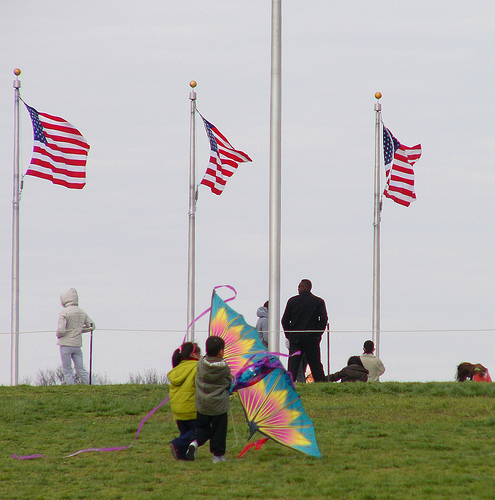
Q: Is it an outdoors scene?
A: Yes, it is outdoors.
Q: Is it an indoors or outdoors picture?
A: It is outdoors.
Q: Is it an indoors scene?
A: No, it is outdoors.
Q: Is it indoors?
A: No, it is outdoors.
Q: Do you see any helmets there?
A: No, there are no helmets.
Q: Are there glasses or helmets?
A: No, there are no helmets or glasses.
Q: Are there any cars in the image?
A: No, there are no cars.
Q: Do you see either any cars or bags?
A: No, there are no cars or bags.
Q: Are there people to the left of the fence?
A: Yes, there is a person to the left of the fence.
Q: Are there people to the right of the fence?
A: No, the person is to the left of the fence.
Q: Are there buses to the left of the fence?
A: No, there is a person to the left of the fence.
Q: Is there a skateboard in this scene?
A: No, there are no skateboards.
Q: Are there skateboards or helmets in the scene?
A: No, there are no skateboards or helmets.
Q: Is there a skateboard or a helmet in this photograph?
A: No, there are no skateboards or helmets.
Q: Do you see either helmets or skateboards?
A: No, there are no skateboards or helmets.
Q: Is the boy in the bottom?
A: Yes, the boy is in the bottom of the image.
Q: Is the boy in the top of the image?
A: No, the boy is in the bottom of the image.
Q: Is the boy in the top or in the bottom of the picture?
A: The boy is in the bottom of the image.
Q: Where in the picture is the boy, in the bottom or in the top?
A: The boy is in the bottom of the image.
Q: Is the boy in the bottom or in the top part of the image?
A: The boy is in the bottom of the image.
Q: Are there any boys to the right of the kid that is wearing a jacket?
A: Yes, there is a boy to the right of the kid.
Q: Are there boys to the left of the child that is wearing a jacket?
A: No, the boy is to the right of the kid.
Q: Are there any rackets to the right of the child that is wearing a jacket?
A: No, there is a boy to the right of the child.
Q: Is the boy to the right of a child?
A: Yes, the boy is to the right of a child.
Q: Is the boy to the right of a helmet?
A: No, the boy is to the right of a child.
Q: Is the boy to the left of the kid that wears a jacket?
A: No, the boy is to the right of the child.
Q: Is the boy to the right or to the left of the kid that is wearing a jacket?
A: The boy is to the right of the kid.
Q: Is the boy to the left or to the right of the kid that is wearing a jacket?
A: The boy is to the right of the kid.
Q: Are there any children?
A: Yes, there is a child.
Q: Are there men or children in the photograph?
A: Yes, there is a child.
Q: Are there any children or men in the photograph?
A: Yes, there is a child.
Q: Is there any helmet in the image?
A: No, there are no helmets.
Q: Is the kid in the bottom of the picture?
A: Yes, the kid is in the bottom of the image.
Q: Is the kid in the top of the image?
A: No, the kid is in the bottom of the image.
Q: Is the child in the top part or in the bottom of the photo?
A: The child is in the bottom of the image.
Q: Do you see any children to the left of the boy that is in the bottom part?
A: Yes, there is a child to the left of the boy.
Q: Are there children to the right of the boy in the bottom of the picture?
A: No, the child is to the left of the boy.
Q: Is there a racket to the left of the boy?
A: No, there is a child to the left of the boy.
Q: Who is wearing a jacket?
A: The kid is wearing a jacket.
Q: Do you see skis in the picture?
A: No, there are no skis.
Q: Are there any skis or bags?
A: No, there are no skis or bags.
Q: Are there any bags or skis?
A: No, there are no skis or bags.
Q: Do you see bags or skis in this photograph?
A: No, there are no skis or bags.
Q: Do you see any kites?
A: Yes, there is a kite.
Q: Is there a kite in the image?
A: Yes, there is a kite.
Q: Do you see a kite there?
A: Yes, there is a kite.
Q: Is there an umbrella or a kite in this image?
A: Yes, there is a kite.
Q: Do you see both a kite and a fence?
A: Yes, there are both a kite and a fence.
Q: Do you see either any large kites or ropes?
A: Yes, there is a large kite.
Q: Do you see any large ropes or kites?
A: Yes, there is a large kite.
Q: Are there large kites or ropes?
A: Yes, there is a large kite.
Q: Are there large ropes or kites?
A: Yes, there is a large kite.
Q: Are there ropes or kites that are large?
A: Yes, the kite is large.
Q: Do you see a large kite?
A: Yes, there is a large kite.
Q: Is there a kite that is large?
A: Yes, there is a kite that is large.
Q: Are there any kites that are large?
A: Yes, there is a kite that is large.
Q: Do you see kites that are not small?
A: Yes, there is a large kite.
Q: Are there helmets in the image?
A: No, there are no helmets.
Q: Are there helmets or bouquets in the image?
A: No, there are no helmets or bouquets.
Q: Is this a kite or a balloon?
A: This is a kite.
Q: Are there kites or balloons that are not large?
A: No, there is a kite but it is large.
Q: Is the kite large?
A: Yes, the kite is large.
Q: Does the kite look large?
A: Yes, the kite is large.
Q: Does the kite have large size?
A: Yes, the kite is large.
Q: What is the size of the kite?
A: The kite is large.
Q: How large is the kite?
A: The kite is large.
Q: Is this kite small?
A: No, the kite is large.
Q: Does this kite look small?
A: No, the kite is large.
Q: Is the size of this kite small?
A: No, the kite is large.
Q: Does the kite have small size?
A: No, the kite is large.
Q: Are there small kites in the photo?
A: No, there is a kite but it is large.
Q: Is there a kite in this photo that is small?
A: No, there is a kite but it is large.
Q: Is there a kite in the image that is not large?
A: No, there is a kite but it is large.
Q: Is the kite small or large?
A: The kite is large.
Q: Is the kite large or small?
A: The kite is large.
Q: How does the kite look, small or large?
A: The kite is large.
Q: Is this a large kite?
A: Yes, this is a large kite.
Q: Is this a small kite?
A: No, this is a large kite.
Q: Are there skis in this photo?
A: No, there are no skis.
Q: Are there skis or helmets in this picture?
A: No, there are no skis or helmets.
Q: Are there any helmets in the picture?
A: No, there are no helmets.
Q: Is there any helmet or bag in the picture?
A: No, there are no helmets or bags.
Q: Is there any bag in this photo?
A: No, there are no bags.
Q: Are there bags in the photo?
A: No, there are no bags.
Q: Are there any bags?
A: No, there are no bags.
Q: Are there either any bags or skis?
A: No, there are no bags or skis.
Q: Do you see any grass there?
A: Yes, there is grass.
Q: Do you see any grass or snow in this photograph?
A: Yes, there is grass.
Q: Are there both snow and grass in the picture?
A: No, there is grass but no snow.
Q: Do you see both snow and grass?
A: No, there is grass but no snow.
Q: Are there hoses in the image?
A: No, there are no hoses.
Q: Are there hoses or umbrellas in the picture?
A: No, there are no hoses or umbrellas.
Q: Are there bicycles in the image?
A: No, there are no bicycles.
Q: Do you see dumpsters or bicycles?
A: No, there are no bicycles or dumpsters.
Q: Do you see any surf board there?
A: No, there are no surfboards.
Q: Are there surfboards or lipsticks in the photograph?
A: No, there are no surfboards or lipsticks.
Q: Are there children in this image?
A: Yes, there are children.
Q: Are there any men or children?
A: Yes, there are children.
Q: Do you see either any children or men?
A: Yes, there are children.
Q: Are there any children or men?
A: Yes, there are children.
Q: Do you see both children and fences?
A: Yes, there are both children and a fence.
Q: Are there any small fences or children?
A: Yes, there are small children.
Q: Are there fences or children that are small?
A: Yes, the children are small.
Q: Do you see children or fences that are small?
A: Yes, the children are small.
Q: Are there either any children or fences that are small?
A: Yes, the children are small.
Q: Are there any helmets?
A: No, there are no helmets.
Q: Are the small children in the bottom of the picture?
A: Yes, the children are in the bottom of the image.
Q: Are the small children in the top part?
A: No, the kids are in the bottom of the image.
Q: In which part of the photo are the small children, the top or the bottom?
A: The children are in the bottom of the image.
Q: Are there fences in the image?
A: Yes, there is a fence.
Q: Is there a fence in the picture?
A: Yes, there is a fence.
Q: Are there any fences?
A: Yes, there is a fence.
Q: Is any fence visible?
A: Yes, there is a fence.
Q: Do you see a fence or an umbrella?
A: Yes, there is a fence.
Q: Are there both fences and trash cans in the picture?
A: No, there is a fence but no trash cans.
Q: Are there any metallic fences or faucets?
A: Yes, there is a metal fence.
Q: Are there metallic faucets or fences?
A: Yes, there is a metal fence.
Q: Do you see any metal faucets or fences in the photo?
A: Yes, there is a metal fence.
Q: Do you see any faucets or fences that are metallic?
A: Yes, the fence is metallic.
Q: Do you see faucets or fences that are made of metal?
A: Yes, the fence is made of metal.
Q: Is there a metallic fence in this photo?
A: Yes, there is a metal fence.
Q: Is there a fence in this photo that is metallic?
A: Yes, there is a fence that is metallic.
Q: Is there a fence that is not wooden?
A: Yes, there is a metallic fence.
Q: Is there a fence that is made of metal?
A: Yes, there is a fence that is made of metal.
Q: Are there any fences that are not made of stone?
A: Yes, there is a fence that is made of metal.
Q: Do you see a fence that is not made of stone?
A: Yes, there is a fence that is made of metal.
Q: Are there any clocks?
A: No, there are no clocks.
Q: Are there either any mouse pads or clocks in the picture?
A: No, there are no clocks or mouse pads.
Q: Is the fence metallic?
A: Yes, the fence is metallic.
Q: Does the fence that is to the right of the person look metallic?
A: Yes, the fence is metallic.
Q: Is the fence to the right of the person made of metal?
A: Yes, the fence is made of metal.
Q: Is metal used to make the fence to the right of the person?
A: Yes, the fence is made of metal.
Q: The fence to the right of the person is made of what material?
A: The fence is made of metal.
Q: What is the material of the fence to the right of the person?
A: The fence is made of metal.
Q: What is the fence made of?
A: The fence is made of metal.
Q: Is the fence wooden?
A: No, the fence is metallic.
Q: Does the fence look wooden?
A: No, the fence is metallic.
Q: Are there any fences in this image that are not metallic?
A: No, there is a fence but it is metallic.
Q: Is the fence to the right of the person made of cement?
A: No, the fence is made of metal.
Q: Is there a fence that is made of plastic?
A: No, there is a fence but it is made of metal.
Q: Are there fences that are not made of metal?
A: No, there is a fence but it is made of metal.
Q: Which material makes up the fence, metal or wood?
A: The fence is made of metal.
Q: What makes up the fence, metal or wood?
A: The fence is made of metal.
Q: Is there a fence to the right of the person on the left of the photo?
A: Yes, there is a fence to the right of the person.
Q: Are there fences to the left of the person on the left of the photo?
A: No, the fence is to the right of the person.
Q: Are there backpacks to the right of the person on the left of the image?
A: No, there is a fence to the right of the person.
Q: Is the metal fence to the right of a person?
A: Yes, the fence is to the right of a person.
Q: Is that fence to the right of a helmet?
A: No, the fence is to the right of a person.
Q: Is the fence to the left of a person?
A: No, the fence is to the right of a person.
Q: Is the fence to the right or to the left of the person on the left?
A: The fence is to the right of the person.